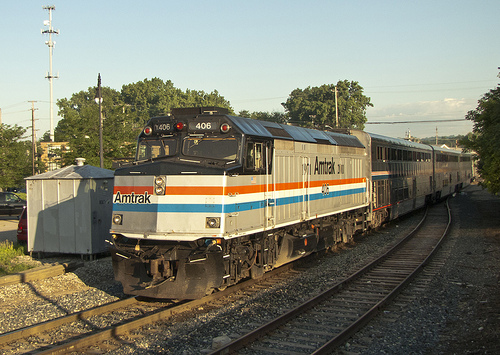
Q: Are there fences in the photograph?
A: No, there are no fences.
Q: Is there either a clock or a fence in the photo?
A: No, there are no fences or clocks.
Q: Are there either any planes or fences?
A: No, there are no fences or planes.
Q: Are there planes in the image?
A: No, there are no planes.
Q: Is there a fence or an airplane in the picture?
A: No, there are no airplanes or fences.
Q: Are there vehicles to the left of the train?
A: Yes, there is a vehicle to the left of the train.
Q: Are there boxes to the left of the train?
A: No, there is a vehicle to the left of the train.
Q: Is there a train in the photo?
A: Yes, there is a train.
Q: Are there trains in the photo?
A: Yes, there is a train.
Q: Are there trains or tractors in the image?
A: Yes, there is a train.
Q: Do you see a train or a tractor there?
A: Yes, there is a train.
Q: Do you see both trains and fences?
A: No, there is a train but no fences.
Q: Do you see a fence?
A: No, there are no fences.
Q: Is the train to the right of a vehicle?
A: Yes, the train is to the right of a vehicle.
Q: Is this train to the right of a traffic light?
A: No, the train is to the right of a vehicle.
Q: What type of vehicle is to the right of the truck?
A: The vehicle is a train.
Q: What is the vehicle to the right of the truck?
A: The vehicle is a train.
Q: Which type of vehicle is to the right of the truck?
A: The vehicle is a train.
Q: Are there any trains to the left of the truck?
A: No, the train is to the right of the truck.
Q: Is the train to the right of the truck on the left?
A: Yes, the train is to the right of the truck.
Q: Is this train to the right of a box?
A: No, the train is to the right of the truck.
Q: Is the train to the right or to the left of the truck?
A: The train is to the right of the truck.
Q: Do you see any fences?
A: No, there are no fences.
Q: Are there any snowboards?
A: No, there are no snowboards.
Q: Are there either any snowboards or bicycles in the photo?
A: No, there are no snowboards or bicycles.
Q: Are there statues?
A: No, there are no statues.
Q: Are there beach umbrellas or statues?
A: No, there are no statues or beach umbrellas.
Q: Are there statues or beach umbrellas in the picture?
A: No, there are no statues or beach umbrellas.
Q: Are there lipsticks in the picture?
A: No, there are no lipsticks.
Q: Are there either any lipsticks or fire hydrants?
A: No, there are no lipsticks or fire hydrants.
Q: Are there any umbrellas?
A: No, there are no umbrellas.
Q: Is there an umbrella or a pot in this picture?
A: No, there are no umbrellas or pots.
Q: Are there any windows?
A: Yes, there is a window.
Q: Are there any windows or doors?
A: Yes, there is a window.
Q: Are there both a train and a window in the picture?
A: Yes, there are both a window and a train.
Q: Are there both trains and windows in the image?
A: Yes, there are both a window and a train.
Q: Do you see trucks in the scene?
A: Yes, there is a truck.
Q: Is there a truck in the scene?
A: Yes, there is a truck.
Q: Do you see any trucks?
A: Yes, there is a truck.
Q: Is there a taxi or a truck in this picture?
A: Yes, there is a truck.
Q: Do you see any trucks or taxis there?
A: Yes, there is a truck.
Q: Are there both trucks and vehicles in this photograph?
A: Yes, there are both a truck and a vehicle.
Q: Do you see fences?
A: No, there are no fences.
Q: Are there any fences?
A: No, there are no fences.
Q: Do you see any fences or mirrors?
A: No, there are no fences or mirrors.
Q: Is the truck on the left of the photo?
A: Yes, the truck is on the left of the image.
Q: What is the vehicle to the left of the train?
A: The vehicle is a truck.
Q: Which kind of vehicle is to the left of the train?
A: The vehicle is a truck.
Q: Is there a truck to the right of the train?
A: No, the truck is to the left of the train.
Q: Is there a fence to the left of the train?
A: No, there is a truck to the left of the train.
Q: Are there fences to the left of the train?
A: No, there is a truck to the left of the train.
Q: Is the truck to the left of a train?
A: Yes, the truck is to the left of a train.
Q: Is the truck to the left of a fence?
A: No, the truck is to the left of a train.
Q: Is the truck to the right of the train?
A: No, the truck is to the left of the train.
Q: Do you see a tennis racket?
A: No, there are no rackets.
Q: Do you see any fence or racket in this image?
A: No, there are no rackets or fences.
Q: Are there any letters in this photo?
A: Yes, there are letters.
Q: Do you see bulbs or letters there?
A: Yes, there are letters.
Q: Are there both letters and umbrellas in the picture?
A: No, there are letters but no umbrellas.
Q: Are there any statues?
A: No, there are no statues.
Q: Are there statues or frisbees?
A: No, there are no statues or frisbees.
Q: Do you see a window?
A: Yes, there is a window.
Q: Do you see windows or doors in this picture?
A: Yes, there is a window.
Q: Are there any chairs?
A: No, there are no chairs.